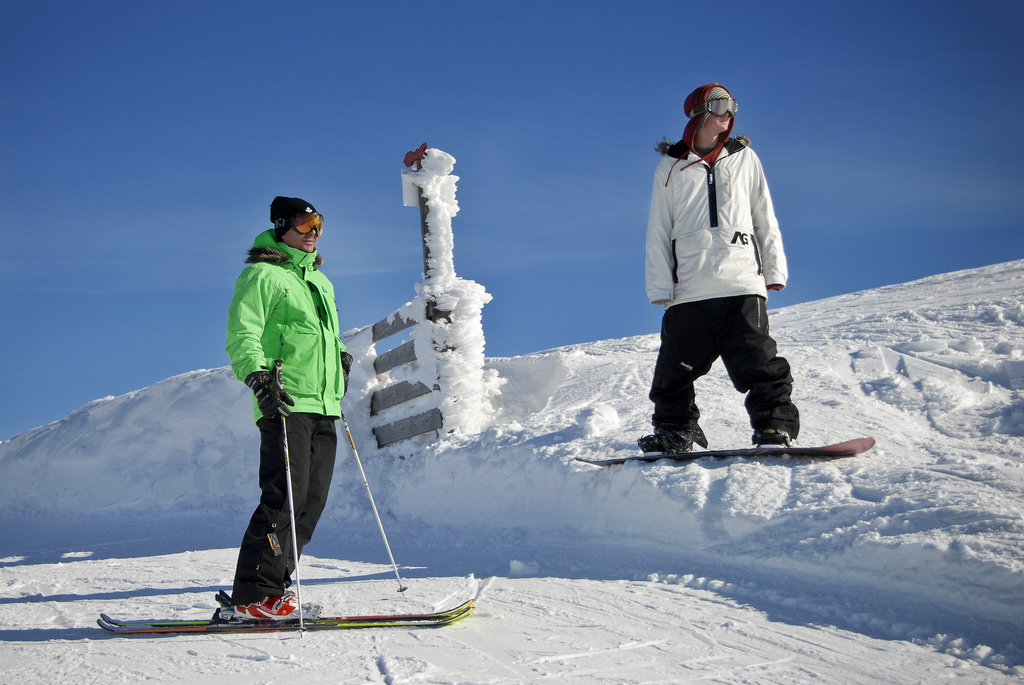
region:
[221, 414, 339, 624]
person has on pants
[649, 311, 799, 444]
person has on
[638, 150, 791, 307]
person has on a jacket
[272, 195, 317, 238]
person has on a jacket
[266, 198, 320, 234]
person has on a hat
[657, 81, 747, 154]
person has on a hat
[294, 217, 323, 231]
person has on goggles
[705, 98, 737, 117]
person has on goggles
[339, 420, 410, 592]
person has skies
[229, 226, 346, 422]
A green coat with hood.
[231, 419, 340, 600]
Black pants on a green coat man.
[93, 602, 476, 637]
Grey, orange and yellow skis on a man.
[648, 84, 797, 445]
Guy in goggles and white coat on a snowboard.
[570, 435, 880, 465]
A snowboard in the snow.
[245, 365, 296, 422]
A black glove on a man's right hand.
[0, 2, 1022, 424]
A blue sky above.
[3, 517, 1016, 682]
A lower section of snow.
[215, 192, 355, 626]
A man standing on skis in a green coat.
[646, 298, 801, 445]
A baggy pair of black pants on a guy in a white coat.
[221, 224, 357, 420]
a bright green ski jacket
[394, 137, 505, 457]
snow stuck on the side of a pole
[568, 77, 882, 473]
a boy on a snowboard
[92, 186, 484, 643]
a man on skis with ski poles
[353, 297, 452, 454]
part of a fence not covered in snow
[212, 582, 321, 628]
red and white ski boots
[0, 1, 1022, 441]
bright blue sky with wispy clouds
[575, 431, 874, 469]
a snowboard with a red bottom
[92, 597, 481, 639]
yellow and orange skis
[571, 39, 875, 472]
Person on a snowboard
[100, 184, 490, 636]
Man on skis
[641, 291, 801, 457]
Droopy black snowpants on the snowboarder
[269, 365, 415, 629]
Ski poles in the man's hands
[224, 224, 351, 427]
Green snow jacket on the man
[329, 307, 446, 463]
Snow-covered fence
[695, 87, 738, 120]
Goggles on the snowboarder's face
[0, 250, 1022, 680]
Snow covering the ground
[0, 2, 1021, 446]
Cloudless blue sky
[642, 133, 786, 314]
White jacket on the snowboarder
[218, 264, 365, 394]
a man wearing a green coat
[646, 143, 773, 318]
a man wearing a white coat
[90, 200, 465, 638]
a person is on the snow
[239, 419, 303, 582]
leg of a person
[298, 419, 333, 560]
leg of a person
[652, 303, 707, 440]
leg of a person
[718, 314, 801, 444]
leg of a person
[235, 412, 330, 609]
the pants are black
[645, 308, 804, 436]
the pants are black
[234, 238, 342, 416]
the jacket is green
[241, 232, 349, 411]
jacket on a person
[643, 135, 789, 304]
jacket on a person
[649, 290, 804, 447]
pants on a person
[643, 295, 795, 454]
the pants are black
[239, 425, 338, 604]
the pants are black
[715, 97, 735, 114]
goggles on the face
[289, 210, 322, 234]
goggles on the face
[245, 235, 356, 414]
a man wearing a green coat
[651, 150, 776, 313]
a man wearing a white and black coat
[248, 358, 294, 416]
a man wearing black gloves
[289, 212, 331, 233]
a man wearing orange goggles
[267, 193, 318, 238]
a man wearing a black hat